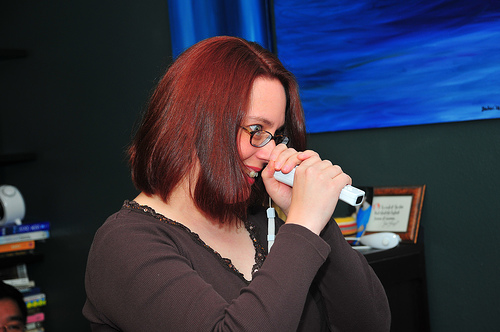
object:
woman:
[83, 37, 396, 332]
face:
[212, 73, 286, 205]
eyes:
[245, 122, 263, 133]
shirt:
[80, 198, 394, 331]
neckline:
[130, 184, 272, 283]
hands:
[257, 139, 317, 229]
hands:
[285, 156, 353, 230]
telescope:
[272, 165, 366, 207]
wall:
[0, 0, 498, 329]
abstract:
[165, 0, 499, 134]